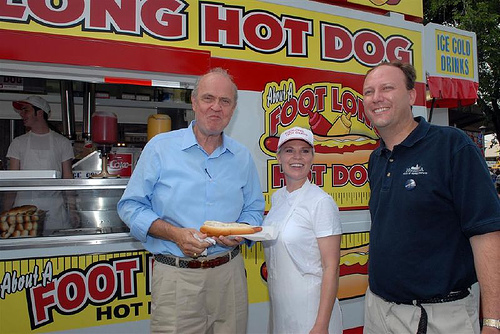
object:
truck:
[0, 3, 480, 331]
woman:
[261, 126, 346, 332]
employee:
[260, 127, 346, 334]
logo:
[260, 76, 395, 234]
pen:
[195, 166, 217, 181]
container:
[146, 113, 172, 140]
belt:
[152, 244, 242, 270]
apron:
[258, 178, 343, 334]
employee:
[4, 95, 79, 229]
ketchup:
[87, 107, 116, 143]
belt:
[363, 287, 469, 333]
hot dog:
[197, 220, 257, 237]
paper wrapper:
[221, 225, 282, 242]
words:
[199, 3, 311, 58]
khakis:
[149, 253, 247, 332]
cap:
[276, 127, 314, 148]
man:
[352, 51, 499, 332]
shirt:
[362, 113, 497, 303]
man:
[117, 65, 271, 333]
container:
[86, 112, 120, 179]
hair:
[190, 68, 240, 98]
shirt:
[118, 110, 265, 260]